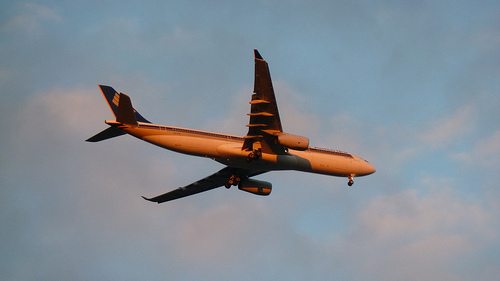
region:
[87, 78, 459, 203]
a big airplane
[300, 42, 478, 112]
the sky is blue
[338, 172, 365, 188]
the plane has a wheel in front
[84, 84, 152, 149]
the plane has wings on the back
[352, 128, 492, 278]
faint clouds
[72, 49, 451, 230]
the plane is white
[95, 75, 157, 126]
the wing is blue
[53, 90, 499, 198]
the plane is long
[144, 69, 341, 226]
two wings on each side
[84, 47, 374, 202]
the plane is in the sky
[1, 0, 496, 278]
the sky has clouds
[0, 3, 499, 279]
the sky is blue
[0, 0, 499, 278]
the clouds are wispy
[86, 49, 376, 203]
the plane has sunlight bouncing from it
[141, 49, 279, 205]
the airplane has two wings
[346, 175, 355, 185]
the wheel is extended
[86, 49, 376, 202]
the plane is alone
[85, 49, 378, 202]
the airplane is the color white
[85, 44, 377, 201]
the plane has shadows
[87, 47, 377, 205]
Plane flying to the right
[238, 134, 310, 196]
Two plane engines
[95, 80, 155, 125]
Tail rudder of the plane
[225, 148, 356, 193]
Extended landing gear of the plane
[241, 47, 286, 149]
Right wing of the plane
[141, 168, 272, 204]
Left wing of the plane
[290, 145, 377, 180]
Front part of the plane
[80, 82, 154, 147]
Tail section of the plane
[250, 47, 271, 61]
Right wingtip of the plane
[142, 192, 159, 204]
Left wingtip of the plane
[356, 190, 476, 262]
Cloud in the sky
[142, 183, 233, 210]
Wing farthest away from us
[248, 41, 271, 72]
Tip of the wing closest to us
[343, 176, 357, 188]
Two wheels underneath the front of the plane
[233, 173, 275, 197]
Engine farthest away from us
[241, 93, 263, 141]
Ridged orange parts under the wing closest to us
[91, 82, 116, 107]
Tip of the tail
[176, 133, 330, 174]
Body of the plane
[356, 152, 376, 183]
Tip/nose of the plane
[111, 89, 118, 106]
Three orange bars on the tail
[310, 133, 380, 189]
Front of an airplane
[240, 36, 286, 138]
Wing of an airplane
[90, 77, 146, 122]
Tail wing of an airplane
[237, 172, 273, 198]
Engine of an airplane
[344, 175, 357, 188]
Wheels of an airplane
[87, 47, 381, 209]
An airplane in flight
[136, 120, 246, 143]
Windows along the side of an airplane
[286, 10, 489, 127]
A cloudy sky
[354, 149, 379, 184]
Cockpit of an airplane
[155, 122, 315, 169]
Passenger section of an airplane